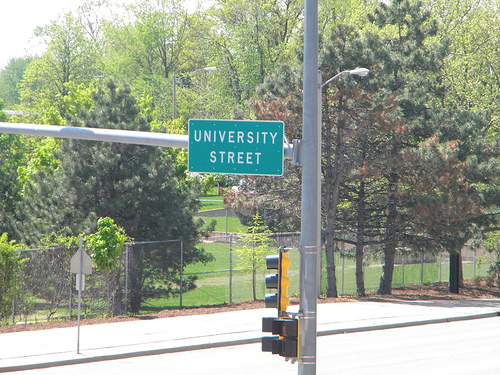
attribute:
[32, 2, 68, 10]
sky — white, clear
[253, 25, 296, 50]
tree — evergreen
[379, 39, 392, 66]
leaves — turning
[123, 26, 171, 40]
trees — distant, rowed, green, tall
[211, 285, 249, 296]
grass — green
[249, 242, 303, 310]
traffic light — yellow, black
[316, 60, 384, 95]
street lamp — metal, glass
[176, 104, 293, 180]
street sign — metal, university street, green, white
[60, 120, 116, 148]
pole — metal, gray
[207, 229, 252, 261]
fence — chain link, metal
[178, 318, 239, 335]
sidewalk — empty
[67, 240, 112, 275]
school sign — backwards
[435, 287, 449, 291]
pinstraw — dark brown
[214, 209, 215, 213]
parking lot — distant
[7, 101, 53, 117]
roof — gray, distant